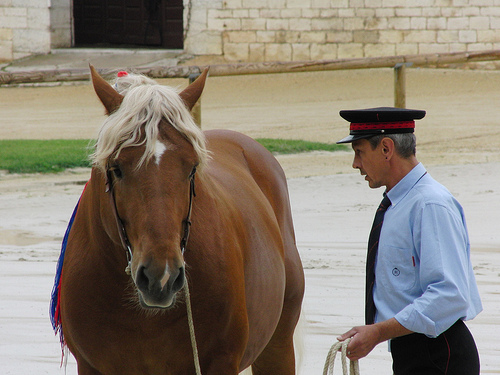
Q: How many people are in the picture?
A: One.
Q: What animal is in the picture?
A: A horse.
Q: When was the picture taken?
A: Daytime.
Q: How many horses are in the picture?
A: 1.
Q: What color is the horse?
A: Brown.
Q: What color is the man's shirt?
A: Blue.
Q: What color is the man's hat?
A: Black with red band.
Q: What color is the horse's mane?
A: White.